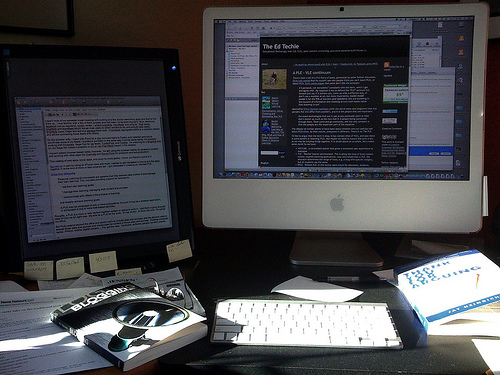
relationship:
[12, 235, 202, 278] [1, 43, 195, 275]
edge of computer.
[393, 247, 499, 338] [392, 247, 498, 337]
white blue book.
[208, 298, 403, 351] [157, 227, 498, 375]
keyboard on desk.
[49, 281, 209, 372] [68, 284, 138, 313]
book about blogging.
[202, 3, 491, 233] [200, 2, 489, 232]
white computer monitor.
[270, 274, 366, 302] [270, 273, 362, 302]
paper. of paper.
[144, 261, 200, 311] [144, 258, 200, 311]
pair of glasses.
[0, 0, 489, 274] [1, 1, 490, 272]
two computer monitors.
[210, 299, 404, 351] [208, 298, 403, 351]
white computer keyboard.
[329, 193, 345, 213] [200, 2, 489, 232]
logo on monitor.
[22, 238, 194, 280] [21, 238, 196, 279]
notes across bottom.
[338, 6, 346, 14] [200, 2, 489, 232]
camera on monitor.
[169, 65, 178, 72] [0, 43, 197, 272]
light on monitor.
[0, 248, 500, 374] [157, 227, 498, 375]
sun on desk.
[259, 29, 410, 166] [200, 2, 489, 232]
website on monitor.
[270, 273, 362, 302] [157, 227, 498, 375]
paper on desk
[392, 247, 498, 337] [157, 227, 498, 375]
book on table.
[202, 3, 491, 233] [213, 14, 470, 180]
white frame screen.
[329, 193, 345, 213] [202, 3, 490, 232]
apple on frame.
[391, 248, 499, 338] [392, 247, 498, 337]
blue white book.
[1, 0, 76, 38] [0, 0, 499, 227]
frame on wall.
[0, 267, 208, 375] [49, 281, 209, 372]
papers under book.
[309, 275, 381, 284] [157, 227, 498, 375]
pen on desk.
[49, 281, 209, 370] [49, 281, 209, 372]
black white book.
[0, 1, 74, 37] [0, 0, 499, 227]
picture on wall.